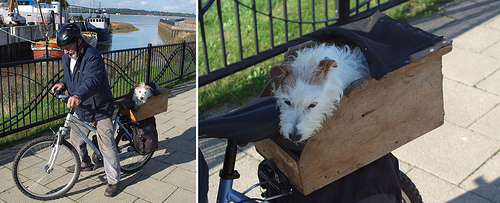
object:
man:
[53, 23, 123, 197]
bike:
[11, 81, 169, 201]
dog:
[130, 82, 154, 110]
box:
[116, 86, 169, 122]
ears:
[135, 83, 141, 88]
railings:
[1, 42, 196, 136]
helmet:
[56, 22, 83, 47]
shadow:
[118, 126, 197, 192]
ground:
[2, 43, 197, 201]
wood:
[117, 85, 168, 122]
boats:
[85, 4, 113, 31]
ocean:
[66, 11, 198, 54]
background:
[1, 2, 196, 64]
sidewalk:
[2, 78, 197, 202]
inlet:
[68, 16, 137, 34]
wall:
[1, 29, 56, 66]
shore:
[67, 5, 195, 19]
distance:
[60, 2, 197, 16]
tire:
[116, 121, 159, 175]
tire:
[11, 134, 82, 201]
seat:
[113, 99, 136, 110]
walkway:
[200, 2, 500, 202]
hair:
[137, 83, 147, 90]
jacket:
[60, 42, 116, 122]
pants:
[69, 107, 121, 185]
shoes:
[98, 181, 119, 195]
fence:
[198, 2, 403, 88]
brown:
[270, 65, 293, 88]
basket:
[256, 13, 454, 195]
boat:
[31, 31, 100, 62]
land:
[108, 20, 139, 34]